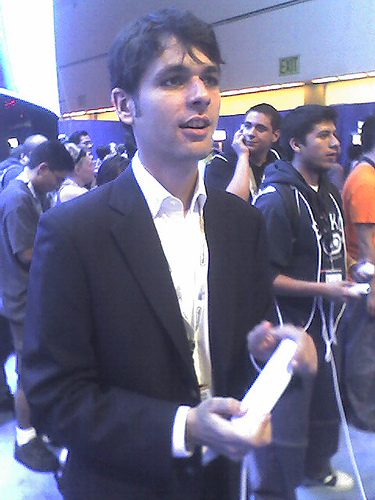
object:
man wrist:
[321, 281, 328, 297]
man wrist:
[366, 288, 375, 297]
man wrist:
[235, 150, 249, 157]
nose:
[186, 77, 212, 108]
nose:
[329, 135, 340, 149]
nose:
[247, 127, 256, 138]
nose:
[55, 182, 60, 190]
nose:
[87, 142, 92, 150]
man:
[0, 139, 75, 481]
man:
[340, 112, 374, 433]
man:
[68, 129, 94, 154]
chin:
[178, 135, 213, 160]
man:
[19, 6, 319, 499]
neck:
[139, 154, 201, 193]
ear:
[111, 83, 136, 126]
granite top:
[327, 151, 337, 159]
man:
[251, 103, 375, 493]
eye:
[160, 76, 185, 90]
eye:
[202, 73, 221, 87]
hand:
[185, 394, 278, 464]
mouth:
[179, 113, 210, 136]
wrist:
[185, 411, 195, 447]